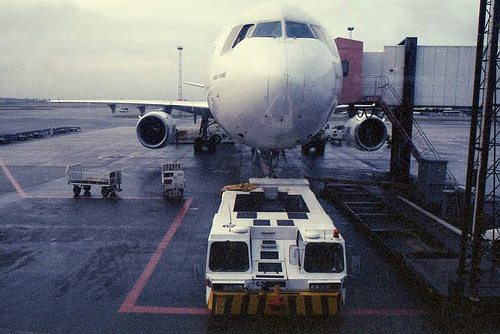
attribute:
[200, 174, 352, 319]
machine — white, yellow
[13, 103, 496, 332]
pavement — black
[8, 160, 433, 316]
lines — red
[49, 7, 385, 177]
plane — large, white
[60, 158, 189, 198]
carts — white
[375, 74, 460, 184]
stairs — metal 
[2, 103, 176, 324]
runway — black , asphalt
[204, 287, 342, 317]
paint — yellow, black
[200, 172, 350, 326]
truck — carrier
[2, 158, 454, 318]
line — red, painted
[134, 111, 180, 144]
engine — large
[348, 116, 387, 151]
engine — large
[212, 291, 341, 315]
stripes — yellow, black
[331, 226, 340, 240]
light — orange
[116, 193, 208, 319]
line — red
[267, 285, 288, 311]
fixture — red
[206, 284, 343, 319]
stripes — yellow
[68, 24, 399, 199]
plane — large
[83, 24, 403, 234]
plane — ready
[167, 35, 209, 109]
tower — large